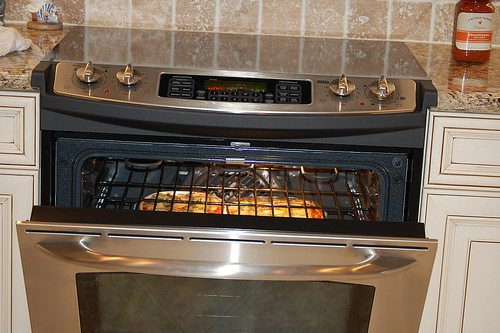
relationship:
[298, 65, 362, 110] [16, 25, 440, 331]
knob on oven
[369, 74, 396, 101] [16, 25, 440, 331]
knob on oven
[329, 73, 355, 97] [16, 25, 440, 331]
knob on oven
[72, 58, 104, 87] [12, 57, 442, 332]
knob on oven